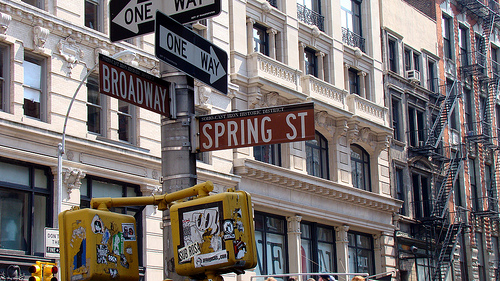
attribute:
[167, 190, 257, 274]
light — yellow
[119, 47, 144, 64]
lights — yellow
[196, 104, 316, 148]
sign — red, white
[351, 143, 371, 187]
window — arched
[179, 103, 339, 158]
sign — red, black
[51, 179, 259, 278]
street lights — yellow, metal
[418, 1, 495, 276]
stairs — black, metal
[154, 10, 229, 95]
sign — black, white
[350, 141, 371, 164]
arch — rounded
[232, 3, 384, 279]
building — brown, tall